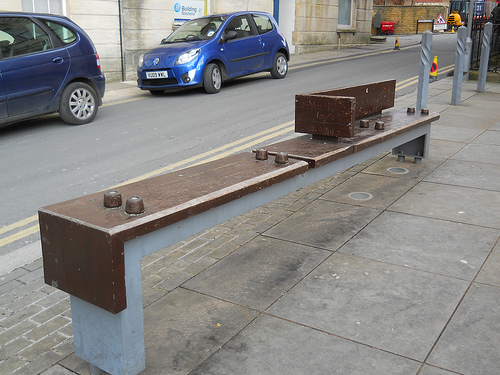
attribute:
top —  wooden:
[33, 149, 308, 314]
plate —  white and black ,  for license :
[144, 68, 169, 78]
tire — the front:
[193, 61, 233, 101]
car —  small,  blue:
[0, 9, 105, 129]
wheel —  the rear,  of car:
[272, 54, 290, 79]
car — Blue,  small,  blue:
[138, 11, 288, 91]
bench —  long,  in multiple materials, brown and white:
[39, 96, 446, 372]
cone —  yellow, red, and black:
[406, 47, 446, 91]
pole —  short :
[414, 25, 436, 131]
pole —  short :
[449, 19, 471, 110]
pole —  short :
[478, 16, 498, 87]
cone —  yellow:
[423, 43, 452, 93]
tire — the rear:
[56, 79, 98, 127]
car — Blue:
[136, 7, 292, 100]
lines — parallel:
[15, 104, 300, 269]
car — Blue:
[125, 10, 296, 97]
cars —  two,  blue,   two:
[0, 7, 293, 123]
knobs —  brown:
[101, 186, 146, 212]